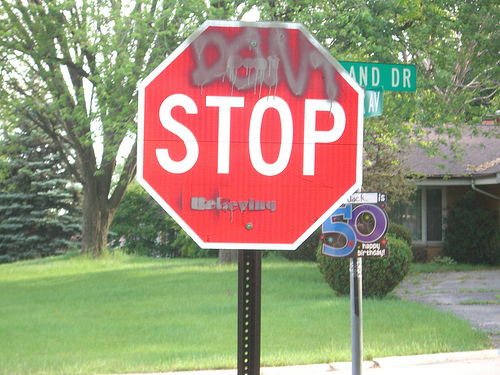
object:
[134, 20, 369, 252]
sign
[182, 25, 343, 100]
graffiti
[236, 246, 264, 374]
pole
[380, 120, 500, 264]
house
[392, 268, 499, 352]
driveway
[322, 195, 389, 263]
sign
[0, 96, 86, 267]
tree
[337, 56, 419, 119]
sign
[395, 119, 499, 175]
roof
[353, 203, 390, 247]
zero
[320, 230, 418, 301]
tree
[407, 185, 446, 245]
window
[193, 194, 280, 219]
graffiti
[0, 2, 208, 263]
tree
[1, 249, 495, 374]
grass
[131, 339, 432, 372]
street